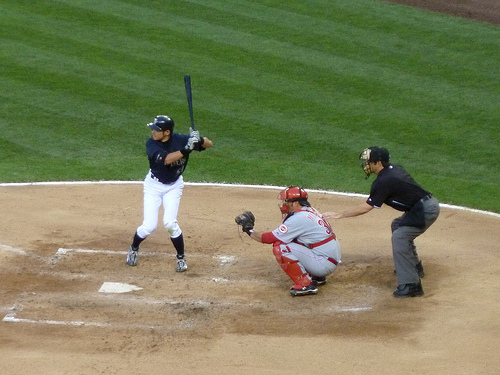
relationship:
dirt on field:
[1, 184, 496, 374] [1, 2, 500, 375]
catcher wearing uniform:
[238, 187, 342, 296] [264, 213, 343, 279]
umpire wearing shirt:
[323, 147, 441, 297] [368, 165, 430, 210]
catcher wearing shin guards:
[238, 187, 342, 296] [273, 242, 309, 291]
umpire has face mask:
[323, 147, 441, 297] [358, 147, 374, 177]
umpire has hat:
[323, 147, 441, 297] [370, 146, 390, 167]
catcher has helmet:
[238, 187, 342, 296] [280, 185, 308, 200]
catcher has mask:
[238, 187, 342, 296] [278, 186, 289, 217]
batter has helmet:
[128, 116, 212, 273] [145, 115, 175, 133]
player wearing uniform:
[128, 116, 212, 273] [131, 132, 204, 255]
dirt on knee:
[168, 228, 175, 236] [163, 220, 180, 235]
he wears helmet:
[128, 116, 212, 273] [145, 115, 175, 133]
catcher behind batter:
[238, 187, 342, 296] [128, 116, 212, 273]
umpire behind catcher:
[323, 147, 441, 297] [238, 187, 342, 296]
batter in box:
[128, 116, 212, 273] [3, 243, 236, 335]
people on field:
[128, 116, 212, 273] [1, 2, 500, 375]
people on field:
[238, 187, 342, 296] [1, 2, 500, 375]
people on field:
[323, 147, 441, 297] [1, 2, 500, 375]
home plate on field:
[99, 279, 142, 294] [1, 2, 500, 375]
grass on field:
[0, 0, 499, 206] [1, 2, 500, 375]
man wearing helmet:
[128, 116, 212, 273] [145, 115, 175, 133]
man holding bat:
[128, 116, 212, 273] [182, 74, 199, 146]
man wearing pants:
[128, 116, 212, 273] [138, 169, 185, 240]